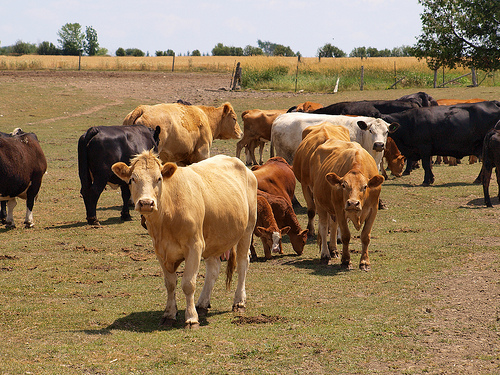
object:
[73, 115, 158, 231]
cows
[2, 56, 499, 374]
pasture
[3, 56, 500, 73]
wheat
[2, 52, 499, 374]
field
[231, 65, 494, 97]
fence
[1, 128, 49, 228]
cow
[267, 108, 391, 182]
cow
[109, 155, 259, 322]
cow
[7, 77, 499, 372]
grass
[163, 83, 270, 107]
manure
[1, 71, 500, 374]
ground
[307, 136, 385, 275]
cow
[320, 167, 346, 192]
ears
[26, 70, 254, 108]
dirt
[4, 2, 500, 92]
background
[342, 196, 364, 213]
snout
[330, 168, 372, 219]
head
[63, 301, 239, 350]
shadow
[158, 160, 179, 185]
ear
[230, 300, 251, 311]
hoof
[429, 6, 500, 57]
leaves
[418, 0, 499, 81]
tree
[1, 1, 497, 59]
sky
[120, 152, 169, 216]
face